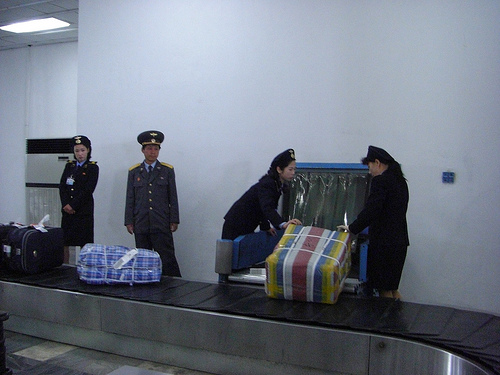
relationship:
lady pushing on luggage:
[335, 141, 412, 307] [260, 216, 356, 309]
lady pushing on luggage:
[211, 144, 305, 274] [260, 216, 356, 309]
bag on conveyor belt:
[74, 241, 171, 292] [3, 257, 493, 374]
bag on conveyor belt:
[3, 215, 67, 280] [3, 257, 493, 374]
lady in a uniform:
[335, 141, 412, 307] [348, 171, 411, 294]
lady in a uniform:
[211, 144, 305, 274] [212, 174, 288, 239]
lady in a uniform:
[54, 134, 102, 260] [58, 158, 100, 246]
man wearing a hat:
[121, 127, 188, 281] [135, 126, 169, 152]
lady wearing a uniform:
[335, 141, 412, 307] [348, 171, 411, 294]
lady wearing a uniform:
[211, 144, 305, 274] [212, 174, 288, 239]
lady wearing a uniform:
[54, 134, 102, 260] [58, 158, 100, 246]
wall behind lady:
[76, 1, 499, 316] [335, 141, 412, 307]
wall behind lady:
[76, 1, 499, 316] [211, 144, 305, 274]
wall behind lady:
[76, 1, 499, 316] [54, 134, 102, 260]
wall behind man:
[76, 1, 499, 316] [121, 127, 188, 281]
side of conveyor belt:
[2, 281, 483, 374] [3, 257, 493, 374]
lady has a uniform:
[335, 141, 412, 307] [348, 171, 411, 294]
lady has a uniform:
[211, 144, 305, 274] [212, 174, 288, 239]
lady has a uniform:
[54, 134, 102, 260] [58, 158, 100, 246]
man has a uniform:
[121, 127, 188, 281] [123, 162, 188, 282]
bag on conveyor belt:
[260, 216, 356, 309] [3, 257, 493, 374]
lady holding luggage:
[335, 141, 412, 307] [260, 216, 356, 309]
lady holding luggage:
[211, 144, 305, 274] [260, 216, 356, 309]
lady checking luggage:
[335, 141, 412, 307] [260, 216, 356, 309]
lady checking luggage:
[211, 144, 305, 274] [260, 216, 356, 309]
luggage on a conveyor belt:
[260, 216, 356, 309] [3, 257, 493, 374]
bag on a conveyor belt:
[74, 241, 171, 292] [3, 257, 493, 374]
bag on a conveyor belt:
[3, 215, 67, 280] [3, 257, 493, 374]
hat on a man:
[135, 126, 169, 152] [121, 127, 188, 281]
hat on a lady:
[70, 135, 93, 149] [54, 134, 102, 260]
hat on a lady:
[271, 144, 298, 175] [211, 144, 305, 274]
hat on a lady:
[366, 143, 398, 167] [335, 141, 412, 307]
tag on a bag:
[111, 246, 140, 270] [74, 241, 171, 292]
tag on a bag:
[32, 222, 51, 237] [3, 215, 67, 280]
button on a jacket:
[147, 181, 152, 187] [124, 157, 182, 239]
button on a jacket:
[148, 189, 155, 195] [124, 157, 182, 239]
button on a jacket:
[147, 198, 153, 202] [124, 157, 182, 239]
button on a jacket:
[148, 206, 156, 213] [124, 157, 182, 239]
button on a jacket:
[70, 188, 75, 192] [58, 157, 99, 214]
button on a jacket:
[69, 196, 74, 200] [58, 157, 99, 214]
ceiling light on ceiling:
[1, 14, 72, 39] [0, 1, 83, 52]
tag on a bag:
[32, 222, 51, 237] [74, 241, 171, 292]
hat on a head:
[135, 126, 169, 152] [135, 127, 167, 167]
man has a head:
[121, 127, 188, 281] [135, 127, 167, 167]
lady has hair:
[335, 141, 412, 307] [360, 156, 408, 182]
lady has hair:
[211, 144, 305, 274] [266, 161, 292, 181]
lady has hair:
[54, 134, 102, 260] [84, 144, 92, 163]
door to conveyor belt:
[287, 168, 373, 240] [3, 257, 493, 374]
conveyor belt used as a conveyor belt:
[3, 257, 493, 374] [3, 257, 493, 374]